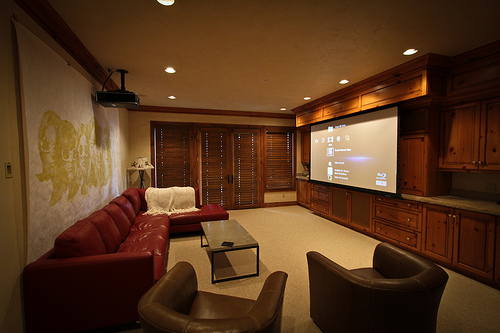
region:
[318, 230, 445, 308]
the seat is curved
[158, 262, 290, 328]
the seat is brown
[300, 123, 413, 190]
projector is on the wall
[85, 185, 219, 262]
the seats are made of leather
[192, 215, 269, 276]
the table is made of glass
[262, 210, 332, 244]
the floor is carpeted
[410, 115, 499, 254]
the cabinets are wooden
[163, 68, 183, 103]
light is on the ceiling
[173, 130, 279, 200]
the window has cabinets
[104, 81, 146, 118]
the projector is hanging from the ceiling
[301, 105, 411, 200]
Black and white projection screen.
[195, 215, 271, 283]
Grey and black coffee table.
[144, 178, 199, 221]
White blanket on sofa.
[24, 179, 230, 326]
Long red leather sofa.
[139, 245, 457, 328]
Two brown leather chairs.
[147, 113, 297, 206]
Brown wooden blinds on windows and doors.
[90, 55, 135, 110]
Black projector hanging from ceiling.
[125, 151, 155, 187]
Lamp in corner near window.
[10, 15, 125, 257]
Gold and white art on wall.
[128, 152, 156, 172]
White lamp shade with designs on it.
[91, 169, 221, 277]
a couch in a room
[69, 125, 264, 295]
a red couch in a room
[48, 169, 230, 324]
a long couch in a room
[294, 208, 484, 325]
a chair in a room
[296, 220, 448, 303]
a brown chair in a room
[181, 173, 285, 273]
a table in a room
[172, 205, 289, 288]
a brown table in a room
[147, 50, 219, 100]
a light in a room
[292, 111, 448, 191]
a screen in a room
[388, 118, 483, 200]
a cabinet in a room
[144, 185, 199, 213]
white blanket on the couch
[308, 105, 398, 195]
large TV screen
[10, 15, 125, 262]
large white tapestry with yellow animals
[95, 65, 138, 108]
large black object on the ceiling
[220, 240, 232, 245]
small black remote control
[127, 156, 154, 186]
floor lamp behind the couch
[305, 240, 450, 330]
brown leather chair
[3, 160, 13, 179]
light switch on the wall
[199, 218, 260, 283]
granite topped coffee table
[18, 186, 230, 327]
red leather sectional couch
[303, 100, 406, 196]
Large projector screen in a living room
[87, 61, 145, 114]
Projector mounted on the ceiling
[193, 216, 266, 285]
Tan and black coffee table.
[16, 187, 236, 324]
Red leather setional sofa with a white throw blanket.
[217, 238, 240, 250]
Remote control for the projector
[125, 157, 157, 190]
Tall black lamp with a white lamp shade.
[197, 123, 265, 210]
Double wooden patio doors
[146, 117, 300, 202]
Windows with wooden blinds that are closed.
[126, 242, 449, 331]
A pair of brown arm chairs sitting in a living room.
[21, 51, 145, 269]
Wall mural with five faces on it.